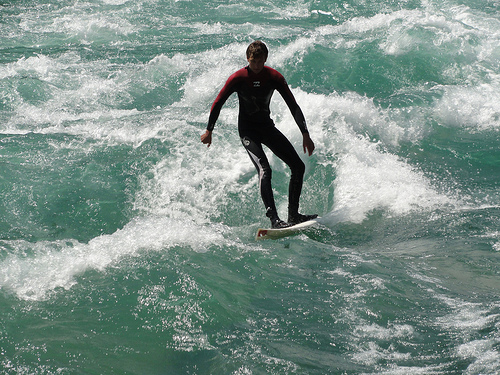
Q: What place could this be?
A: It is an ocean.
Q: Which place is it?
A: It is an ocean.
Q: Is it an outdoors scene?
A: Yes, it is outdoors.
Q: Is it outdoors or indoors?
A: It is outdoors.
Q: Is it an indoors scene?
A: No, it is outdoors.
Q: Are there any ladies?
A: No, there are no ladies.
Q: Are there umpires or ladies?
A: No, there are no ladies or umpires.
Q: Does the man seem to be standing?
A: Yes, the man is standing.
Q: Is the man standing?
A: Yes, the man is standing.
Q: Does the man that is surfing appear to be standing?
A: Yes, the man is standing.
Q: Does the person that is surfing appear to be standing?
A: Yes, the man is standing.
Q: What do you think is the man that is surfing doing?
A: The man is standing.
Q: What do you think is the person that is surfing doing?
A: The man is standing.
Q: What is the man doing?
A: The man is standing.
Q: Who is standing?
A: The man is standing.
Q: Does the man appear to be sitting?
A: No, the man is standing.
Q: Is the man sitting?
A: No, the man is standing.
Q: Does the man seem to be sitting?
A: No, the man is standing.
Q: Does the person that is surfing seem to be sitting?
A: No, the man is standing.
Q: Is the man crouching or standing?
A: The man is standing.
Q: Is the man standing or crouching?
A: The man is standing.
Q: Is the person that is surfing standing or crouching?
A: The man is standing.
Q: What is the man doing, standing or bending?
A: The man is standing.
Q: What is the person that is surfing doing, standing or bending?
A: The man is standing.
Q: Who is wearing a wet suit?
A: The man is wearing a wet suit.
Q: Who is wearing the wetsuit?
A: The man is wearing a wet suit.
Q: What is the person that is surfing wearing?
A: The man is wearing a wetsuit.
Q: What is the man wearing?
A: The man is wearing a wetsuit.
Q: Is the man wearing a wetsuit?
A: Yes, the man is wearing a wetsuit.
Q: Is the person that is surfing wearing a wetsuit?
A: Yes, the man is wearing a wetsuit.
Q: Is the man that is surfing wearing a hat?
A: No, the man is wearing a wetsuit.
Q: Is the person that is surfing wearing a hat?
A: No, the man is wearing a wetsuit.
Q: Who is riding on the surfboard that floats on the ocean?
A: The man is riding on the surfboard.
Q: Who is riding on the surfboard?
A: The man is riding on the surfboard.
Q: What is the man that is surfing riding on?
A: The man is riding on the surf board.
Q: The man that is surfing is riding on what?
A: The man is riding on the surf board.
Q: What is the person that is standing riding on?
A: The man is riding on the surf board.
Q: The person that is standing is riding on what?
A: The man is riding on the surf board.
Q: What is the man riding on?
A: The man is riding on the surf board.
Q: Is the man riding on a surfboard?
A: Yes, the man is riding on a surfboard.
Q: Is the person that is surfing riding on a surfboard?
A: Yes, the man is riding on a surfboard.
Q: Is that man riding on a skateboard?
A: No, the man is riding on a surfboard.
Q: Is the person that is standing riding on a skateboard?
A: No, the man is riding on a surfboard.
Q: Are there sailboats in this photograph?
A: No, there are no sailboats.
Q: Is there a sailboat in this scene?
A: No, there are no sailboats.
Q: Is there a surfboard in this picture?
A: Yes, there is a surfboard.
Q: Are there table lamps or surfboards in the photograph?
A: Yes, there is a surfboard.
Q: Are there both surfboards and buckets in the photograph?
A: No, there is a surfboard but no buckets.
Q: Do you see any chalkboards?
A: No, there are no chalkboards.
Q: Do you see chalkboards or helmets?
A: No, there are no chalkboards or helmets.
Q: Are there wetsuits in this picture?
A: Yes, there is a wetsuit.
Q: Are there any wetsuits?
A: Yes, there is a wetsuit.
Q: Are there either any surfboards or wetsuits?
A: Yes, there is a wetsuit.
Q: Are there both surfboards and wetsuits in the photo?
A: Yes, there are both a wetsuit and a surfboard.